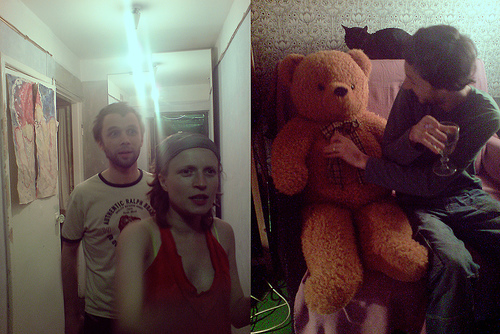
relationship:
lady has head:
[112, 132, 258, 332] [153, 129, 223, 221]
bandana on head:
[158, 131, 222, 180] [153, 129, 223, 221]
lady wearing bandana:
[112, 132, 258, 332] [158, 131, 222, 180]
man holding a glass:
[377, 22, 483, 318] [431, 121, 459, 174]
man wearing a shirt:
[53, 95, 156, 325] [58, 170, 160, 319]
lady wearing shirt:
[112, 132, 258, 332] [124, 206, 243, 326]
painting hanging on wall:
[5, 67, 64, 215] [0, 20, 144, 326]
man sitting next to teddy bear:
[322, 23, 500, 334] [262, 42, 433, 312]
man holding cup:
[322, 23, 500, 334] [429, 117, 460, 176]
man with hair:
[56, 104, 172, 330] [93, 98, 137, 146]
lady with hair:
[112, 132, 258, 332] [150, 134, 227, 232]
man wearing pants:
[322, 23, 500, 334] [409, 180, 482, 310]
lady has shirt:
[124, 132, 259, 331] [124, 206, 238, 334]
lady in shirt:
[112, 132, 258, 332] [136, 215, 239, 332]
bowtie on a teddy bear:
[323, 120, 370, 188] [262, 42, 433, 319]